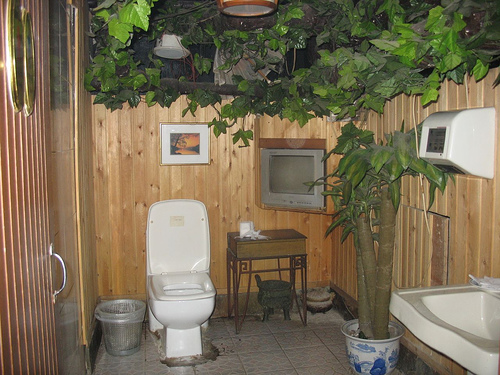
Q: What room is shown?
A: It is a bathroom.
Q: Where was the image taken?
A: It was taken at the bathroom.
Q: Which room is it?
A: It is a bathroom.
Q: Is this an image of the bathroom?
A: Yes, it is showing the bathroom.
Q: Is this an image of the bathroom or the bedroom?
A: It is showing the bathroom.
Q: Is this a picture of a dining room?
A: No, the picture is showing a bathroom.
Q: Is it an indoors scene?
A: Yes, it is indoors.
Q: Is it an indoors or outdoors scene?
A: It is indoors.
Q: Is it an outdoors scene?
A: No, it is indoors.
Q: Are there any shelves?
A: No, there are no shelves.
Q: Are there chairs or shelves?
A: No, there are no shelves or chairs.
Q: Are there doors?
A: Yes, there is a door.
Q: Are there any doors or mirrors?
A: Yes, there is a door.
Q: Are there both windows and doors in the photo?
A: No, there is a door but no windows.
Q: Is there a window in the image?
A: No, there are no windows.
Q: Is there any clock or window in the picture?
A: No, there are no windows or clocks.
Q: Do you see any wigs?
A: No, there are no wigs.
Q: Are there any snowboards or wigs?
A: No, there are no wigs or snowboards.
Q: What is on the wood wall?
A: The picture is on the wall.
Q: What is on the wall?
A: The picture is on the wall.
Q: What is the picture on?
A: The picture is on the wall.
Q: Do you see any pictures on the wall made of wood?
A: Yes, there is a picture on the wall.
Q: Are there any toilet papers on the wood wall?
A: No, there is a picture on the wall.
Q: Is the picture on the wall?
A: Yes, the picture is on the wall.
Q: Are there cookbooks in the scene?
A: No, there are no cookbooks.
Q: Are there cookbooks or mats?
A: No, there are no cookbooks or mats.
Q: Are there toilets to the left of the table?
A: Yes, there is a toilet to the left of the table.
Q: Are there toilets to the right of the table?
A: No, the toilet is to the left of the table.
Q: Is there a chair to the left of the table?
A: No, there is a toilet to the left of the table.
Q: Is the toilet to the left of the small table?
A: Yes, the toilet is to the left of the table.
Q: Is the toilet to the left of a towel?
A: No, the toilet is to the left of the table.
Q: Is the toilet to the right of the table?
A: No, the toilet is to the left of the table.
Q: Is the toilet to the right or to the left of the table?
A: The toilet is to the left of the table.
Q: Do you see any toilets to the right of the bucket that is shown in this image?
A: Yes, there is a toilet to the right of the bucket.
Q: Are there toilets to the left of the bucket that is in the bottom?
A: No, the toilet is to the right of the bucket.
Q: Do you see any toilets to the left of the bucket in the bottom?
A: No, the toilet is to the right of the bucket.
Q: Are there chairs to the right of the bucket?
A: No, there is a toilet to the right of the bucket.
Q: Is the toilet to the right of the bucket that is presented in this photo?
A: Yes, the toilet is to the right of the bucket.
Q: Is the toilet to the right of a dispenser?
A: No, the toilet is to the right of the bucket.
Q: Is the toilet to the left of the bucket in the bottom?
A: No, the toilet is to the right of the bucket.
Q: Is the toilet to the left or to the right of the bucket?
A: The toilet is to the right of the bucket.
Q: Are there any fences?
A: No, there are no fences.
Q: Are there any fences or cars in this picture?
A: No, there are no fences or cars.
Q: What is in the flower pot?
A: The tree is in the flower pot.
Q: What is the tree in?
A: The tree is in the flower pot.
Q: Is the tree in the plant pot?
A: Yes, the tree is in the plant pot.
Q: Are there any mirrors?
A: No, there are no mirrors.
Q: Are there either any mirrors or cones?
A: No, there are no mirrors or cones.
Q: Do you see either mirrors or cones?
A: No, there are no mirrors or cones.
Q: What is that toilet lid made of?
A: The toilet lid is made of plastic.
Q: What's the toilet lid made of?
A: The toilet lid is made of plastic.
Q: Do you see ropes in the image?
A: No, there are no ropes.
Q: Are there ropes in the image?
A: No, there are no ropes.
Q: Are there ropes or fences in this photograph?
A: No, there are no ropes or fences.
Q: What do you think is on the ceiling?
A: The leaves are on the ceiling.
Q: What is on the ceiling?
A: The leaves are on the ceiling.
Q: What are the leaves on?
A: The leaves are on the ceiling.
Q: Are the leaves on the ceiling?
A: Yes, the leaves are on the ceiling.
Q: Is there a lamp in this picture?
A: Yes, there is a lamp.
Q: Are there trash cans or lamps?
A: Yes, there is a lamp.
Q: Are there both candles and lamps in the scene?
A: No, there is a lamp but no candles.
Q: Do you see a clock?
A: No, there are no clocks.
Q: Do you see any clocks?
A: No, there are no clocks.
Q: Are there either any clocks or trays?
A: No, there are no clocks or trays.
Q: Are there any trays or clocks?
A: No, there are no clocks or trays.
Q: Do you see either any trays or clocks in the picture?
A: No, there are no clocks or trays.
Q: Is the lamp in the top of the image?
A: Yes, the lamp is in the top of the image.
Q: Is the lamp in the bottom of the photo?
A: No, the lamp is in the top of the image.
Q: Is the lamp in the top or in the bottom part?
A: The lamp is in the top of the image.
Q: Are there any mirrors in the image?
A: No, there are no mirrors.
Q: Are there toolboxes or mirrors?
A: No, there are no mirrors or toolboxes.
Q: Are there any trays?
A: No, there are no trays.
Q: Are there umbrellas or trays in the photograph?
A: No, there are no trays or umbrellas.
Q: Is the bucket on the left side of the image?
A: Yes, the bucket is on the left of the image.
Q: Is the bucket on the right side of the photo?
A: No, the bucket is on the left of the image.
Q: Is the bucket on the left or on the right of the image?
A: The bucket is on the left of the image.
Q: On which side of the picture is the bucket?
A: The bucket is on the left of the image.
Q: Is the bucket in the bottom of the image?
A: Yes, the bucket is in the bottom of the image.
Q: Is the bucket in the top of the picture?
A: No, the bucket is in the bottom of the image.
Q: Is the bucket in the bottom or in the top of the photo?
A: The bucket is in the bottom of the image.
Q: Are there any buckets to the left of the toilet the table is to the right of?
A: Yes, there is a bucket to the left of the toilet.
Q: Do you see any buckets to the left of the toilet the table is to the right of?
A: Yes, there is a bucket to the left of the toilet.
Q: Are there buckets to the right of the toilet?
A: No, the bucket is to the left of the toilet.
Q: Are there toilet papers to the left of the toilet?
A: No, there is a bucket to the left of the toilet.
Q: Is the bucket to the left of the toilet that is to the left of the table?
A: Yes, the bucket is to the left of the toilet.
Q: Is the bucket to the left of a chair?
A: No, the bucket is to the left of the toilet.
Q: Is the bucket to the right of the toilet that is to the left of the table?
A: No, the bucket is to the left of the toilet.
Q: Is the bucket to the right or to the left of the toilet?
A: The bucket is to the left of the toilet.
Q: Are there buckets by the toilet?
A: Yes, there is a bucket by the toilet.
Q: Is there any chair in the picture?
A: No, there are no chairs.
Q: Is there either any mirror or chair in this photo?
A: No, there are no chairs or mirrors.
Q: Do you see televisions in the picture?
A: Yes, there is a television.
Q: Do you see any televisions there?
A: Yes, there is a television.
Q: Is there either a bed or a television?
A: Yes, there is a television.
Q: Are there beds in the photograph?
A: No, there are no beds.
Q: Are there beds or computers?
A: No, there are no beds or computers.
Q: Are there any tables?
A: Yes, there is a table.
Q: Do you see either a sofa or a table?
A: Yes, there is a table.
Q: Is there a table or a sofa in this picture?
A: Yes, there is a table.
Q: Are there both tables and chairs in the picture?
A: No, there is a table but no chairs.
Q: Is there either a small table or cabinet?
A: Yes, there is a small table.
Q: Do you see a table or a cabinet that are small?
A: Yes, the table is small.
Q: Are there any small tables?
A: Yes, there is a small table.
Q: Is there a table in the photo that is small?
A: Yes, there is a table that is small.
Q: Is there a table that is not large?
A: Yes, there is a small table.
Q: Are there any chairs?
A: No, there are no chairs.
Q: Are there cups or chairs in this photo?
A: No, there are no chairs or cups.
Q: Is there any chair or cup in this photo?
A: No, there are no chairs or cups.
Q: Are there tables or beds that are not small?
A: No, there is a table but it is small.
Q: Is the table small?
A: Yes, the table is small.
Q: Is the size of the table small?
A: Yes, the table is small.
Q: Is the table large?
A: No, the table is small.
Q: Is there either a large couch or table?
A: No, there is a table but it is small.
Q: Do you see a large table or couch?
A: No, there is a table but it is small.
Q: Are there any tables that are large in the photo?
A: No, there is a table but it is small.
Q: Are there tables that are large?
A: No, there is a table but it is small.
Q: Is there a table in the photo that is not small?
A: No, there is a table but it is small.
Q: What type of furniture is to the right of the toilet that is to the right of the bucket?
A: The piece of furniture is a table.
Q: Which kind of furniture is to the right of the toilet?
A: The piece of furniture is a table.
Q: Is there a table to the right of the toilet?
A: Yes, there is a table to the right of the toilet.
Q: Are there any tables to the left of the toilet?
A: No, the table is to the right of the toilet.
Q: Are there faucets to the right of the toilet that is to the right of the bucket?
A: No, there is a table to the right of the toilet.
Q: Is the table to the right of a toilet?
A: Yes, the table is to the right of a toilet.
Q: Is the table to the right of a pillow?
A: No, the table is to the right of a toilet.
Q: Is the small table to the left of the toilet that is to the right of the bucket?
A: No, the table is to the right of the toilet.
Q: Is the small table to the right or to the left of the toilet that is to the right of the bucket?
A: The table is to the right of the toilet.